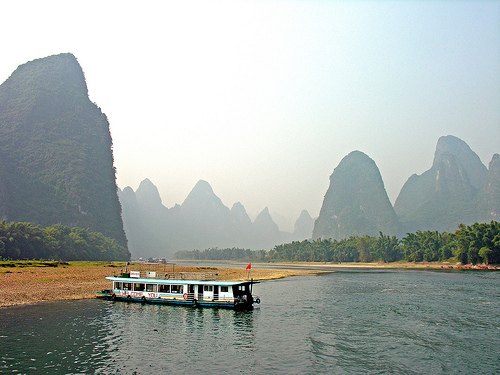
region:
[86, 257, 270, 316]
the boat on the water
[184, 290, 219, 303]
the rail on the side of the boat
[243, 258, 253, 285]
the flag on top of the roof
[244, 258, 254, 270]
the orange flag waving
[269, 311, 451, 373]
the waves in the water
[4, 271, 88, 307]
the dirt bank next to the boat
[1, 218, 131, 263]
the trees on the beach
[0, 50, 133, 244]
the tall mountain face with trees on it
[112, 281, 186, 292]
the windows on the boat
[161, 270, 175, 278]
the circle inflation device on the top deck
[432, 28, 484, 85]
this is the sky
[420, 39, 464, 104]
the sky is blue in color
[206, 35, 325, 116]
the sky has clouds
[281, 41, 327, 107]
the clouds are white in color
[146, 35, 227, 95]
the sky is bright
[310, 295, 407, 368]
this is the water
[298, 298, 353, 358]
the water is blue in color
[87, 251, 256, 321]
this is a boat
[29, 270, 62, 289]
this is the ground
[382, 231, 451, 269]
these are some trees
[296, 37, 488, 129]
Sky is blue color.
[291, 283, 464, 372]
Water is blue color.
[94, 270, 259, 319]
Boat is in water.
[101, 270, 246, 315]
Boat is white color.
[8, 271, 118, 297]
Ground is brown color.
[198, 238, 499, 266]
Trees are green color.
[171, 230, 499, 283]
Trees are behind the water.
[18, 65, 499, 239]
Hills are on both sides of water.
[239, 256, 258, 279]
Flag is orange color.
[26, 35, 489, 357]
Day time picture.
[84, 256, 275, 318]
a boat on the water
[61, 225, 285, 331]
a boat on the water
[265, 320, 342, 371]
the water is blue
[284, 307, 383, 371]
the water is blue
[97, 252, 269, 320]
large ferry boat on water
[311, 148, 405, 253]
large green dome mountain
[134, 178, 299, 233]
several mountains in distance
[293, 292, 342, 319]
calm water with light waves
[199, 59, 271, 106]
lightly cloudy mist sky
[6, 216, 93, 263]
several trees and bushes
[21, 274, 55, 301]
sand on shore of water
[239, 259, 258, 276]
red flag on top of boat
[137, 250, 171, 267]
several boats on water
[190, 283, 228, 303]
door of side in boat